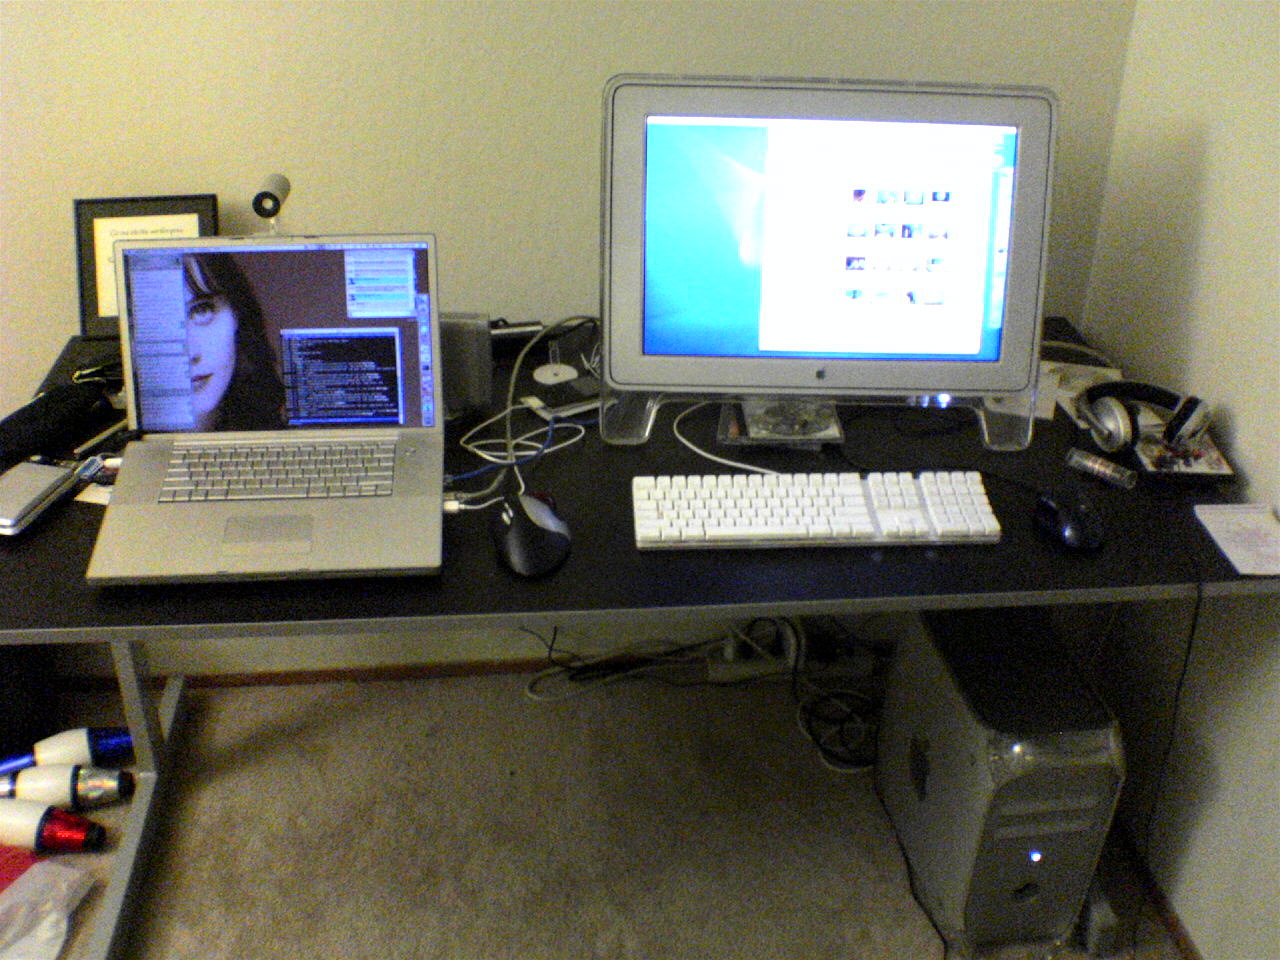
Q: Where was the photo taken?
A: At a desk.